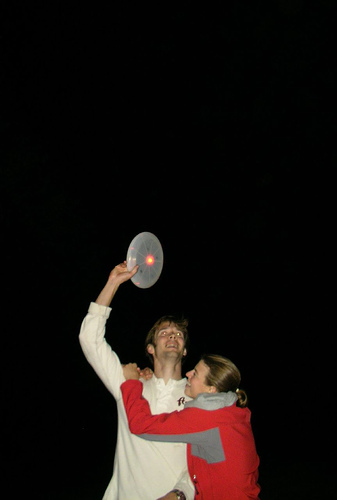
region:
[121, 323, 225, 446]
woman hugging the man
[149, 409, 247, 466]
woman's tops is red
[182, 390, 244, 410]
woman's hoodie is gray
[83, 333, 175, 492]
man's shirt is white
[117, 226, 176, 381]
man is holding frisbee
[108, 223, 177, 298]
the light is red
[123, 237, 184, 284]
light at the center of frisbee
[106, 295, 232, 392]
man is looking up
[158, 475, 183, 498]
the man is wearing watch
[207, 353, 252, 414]
the woman's hair is brown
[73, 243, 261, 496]
a couple hugs at night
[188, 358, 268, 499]
a woman in a red and gray jacket clings to her boyfriend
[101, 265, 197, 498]
a man in a white shirt teases his girlfriend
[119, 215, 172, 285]
a white plastic frisbee lights up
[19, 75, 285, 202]
the sky is a deep, rich black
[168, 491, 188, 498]
a metal watch is worn by a young man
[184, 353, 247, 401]
the young woman wears a ponytail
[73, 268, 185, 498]
a young man hugs his lover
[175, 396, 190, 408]
a red logo is stitched to a white shirt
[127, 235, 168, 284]
a frisbee glows orange in the center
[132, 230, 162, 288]
Frisbee like disc in mans hand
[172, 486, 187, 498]
watch on mans wrist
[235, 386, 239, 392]
white hair band in womans hair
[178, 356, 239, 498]
woman in red and grey hoodie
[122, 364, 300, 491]
woman in red and grey hoodie hugging man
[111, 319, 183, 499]
man in a white shirt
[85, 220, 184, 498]
man in a white shirt holding disc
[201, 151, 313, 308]
black sky in the night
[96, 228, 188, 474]
man looking up into the sky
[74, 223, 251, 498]
man and woman hugging each other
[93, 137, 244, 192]
the sky is black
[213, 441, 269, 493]
the shirt is red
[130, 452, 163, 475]
the shirt is white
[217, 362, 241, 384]
the hair is brown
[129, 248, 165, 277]
the frisbee is white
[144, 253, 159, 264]
the frisbee has an orange light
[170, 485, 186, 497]
the watch is black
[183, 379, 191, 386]
the teeth are white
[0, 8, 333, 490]
the photo was taken at night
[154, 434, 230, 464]
the part of clothing is grey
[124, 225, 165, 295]
a light-up frisbee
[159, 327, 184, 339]
camera flash reflecting off of the eyes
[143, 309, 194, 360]
blonde and brown hair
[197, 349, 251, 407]
hair pulled back into a pony tail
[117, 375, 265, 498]
a red and gray jacket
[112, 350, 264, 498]
a woman holding onto another person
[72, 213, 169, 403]
a raised arm holding a frisbee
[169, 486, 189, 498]
a silver wrist watch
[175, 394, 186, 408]
a red letter "a"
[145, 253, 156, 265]
a red light on a frisbee